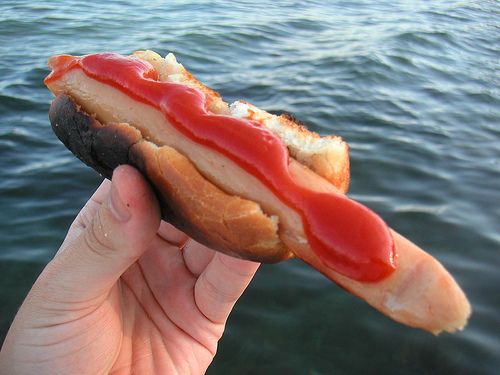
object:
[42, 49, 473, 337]
footlong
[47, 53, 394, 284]
ketchup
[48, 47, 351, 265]
bun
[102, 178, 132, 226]
nail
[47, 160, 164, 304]
thumb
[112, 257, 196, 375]
palm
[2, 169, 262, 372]
hand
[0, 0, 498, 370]
water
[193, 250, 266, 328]
pinky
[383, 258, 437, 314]
mark